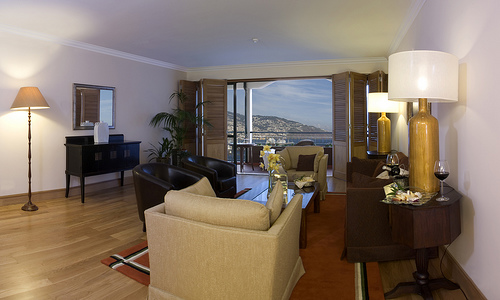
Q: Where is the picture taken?
A: A living room.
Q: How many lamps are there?
A: Three.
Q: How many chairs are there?
A: Four.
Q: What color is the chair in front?
A: Tan.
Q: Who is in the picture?
A: Nobody.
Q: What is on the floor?
A: An area rug.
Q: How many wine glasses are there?
A: Two.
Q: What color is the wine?
A: Red.